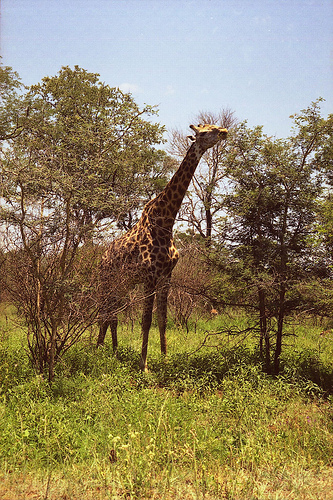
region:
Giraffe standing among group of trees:
[1, 61, 330, 381]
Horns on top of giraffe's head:
[188, 123, 203, 132]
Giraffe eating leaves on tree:
[95, 124, 229, 373]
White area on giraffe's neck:
[192, 141, 202, 160]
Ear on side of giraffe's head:
[187, 132, 196, 142]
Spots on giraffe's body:
[96, 142, 203, 357]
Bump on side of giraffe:
[168, 239, 179, 272]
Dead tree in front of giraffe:
[5, 152, 181, 387]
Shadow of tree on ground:
[296, 356, 332, 399]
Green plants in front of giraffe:
[2, 372, 331, 496]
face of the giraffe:
[185, 112, 251, 171]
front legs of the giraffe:
[126, 308, 192, 373]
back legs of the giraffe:
[82, 309, 120, 348]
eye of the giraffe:
[196, 128, 214, 140]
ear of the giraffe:
[187, 122, 204, 134]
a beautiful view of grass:
[14, 332, 325, 488]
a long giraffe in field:
[40, 96, 258, 428]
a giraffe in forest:
[45, 108, 285, 474]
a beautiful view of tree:
[16, 90, 177, 486]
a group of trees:
[221, 187, 313, 385]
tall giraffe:
[66, 111, 224, 389]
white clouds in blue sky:
[11, 14, 58, 50]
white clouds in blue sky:
[51, 11, 99, 53]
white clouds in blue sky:
[107, 17, 154, 81]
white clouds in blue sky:
[158, 22, 199, 63]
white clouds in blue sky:
[153, 56, 194, 97]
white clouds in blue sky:
[189, 12, 250, 53]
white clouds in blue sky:
[229, 47, 286, 79]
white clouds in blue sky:
[225, 4, 265, 37]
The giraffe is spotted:
[93, 121, 228, 364]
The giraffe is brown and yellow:
[95, 122, 226, 362]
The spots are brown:
[95, 122, 226, 364]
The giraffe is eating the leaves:
[98, 122, 236, 363]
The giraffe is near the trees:
[8, 66, 331, 371]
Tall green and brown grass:
[7, 313, 325, 490]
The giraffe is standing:
[92, 124, 231, 366]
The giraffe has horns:
[186, 123, 206, 132]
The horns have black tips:
[186, 119, 206, 135]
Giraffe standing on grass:
[91, 118, 233, 378]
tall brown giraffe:
[83, 115, 227, 380]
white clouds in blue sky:
[33, 22, 65, 49]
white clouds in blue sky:
[90, 14, 133, 66]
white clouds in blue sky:
[137, 11, 176, 44]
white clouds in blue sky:
[208, 16, 236, 61]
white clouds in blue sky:
[265, 18, 330, 53]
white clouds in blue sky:
[184, 28, 224, 84]